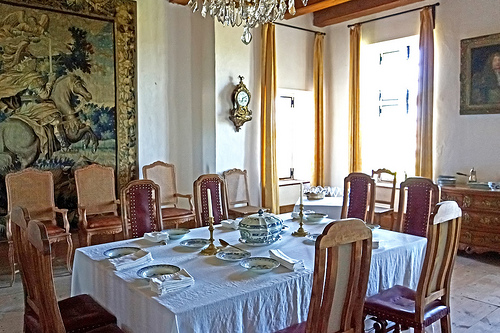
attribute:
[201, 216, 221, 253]
candle holder — brass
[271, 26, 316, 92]
curtain — tan, window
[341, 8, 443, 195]
shades — partially drawn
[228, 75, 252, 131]
clock — white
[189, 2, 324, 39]
chandelier — glass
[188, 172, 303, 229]
candles — white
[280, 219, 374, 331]
chair — seven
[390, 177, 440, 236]
chair — seven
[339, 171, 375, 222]
chair — seven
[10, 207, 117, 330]
chair — seven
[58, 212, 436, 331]
table — dining, seven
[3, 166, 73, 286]
chair — wooden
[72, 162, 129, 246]
chair — wooden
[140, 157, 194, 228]
chair — wooden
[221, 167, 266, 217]
chair — wooden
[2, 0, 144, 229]
art piece — large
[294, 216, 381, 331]
chair — wooden, dining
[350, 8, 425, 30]
rod — dark colored, curtain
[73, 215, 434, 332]
tablecloth — white in color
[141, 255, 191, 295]
bowl — blue and white